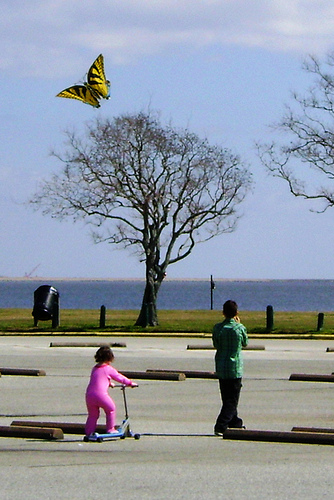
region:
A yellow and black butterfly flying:
[33, 61, 123, 112]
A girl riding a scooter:
[49, 324, 160, 445]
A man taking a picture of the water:
[196, 290, 271, 479]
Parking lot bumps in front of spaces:
[2, 356, 55, 392]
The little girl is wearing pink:
[81, 353, 148, 439]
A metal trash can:
[27, 256, 75, 342]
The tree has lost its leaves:
[48, 156, 246, 338]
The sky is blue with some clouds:
[166, 24, 261, 124]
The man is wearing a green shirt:
[205, 319, 258, 378]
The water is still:
[10, 263, 139, 304]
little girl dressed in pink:
[53, 309, 139, 464]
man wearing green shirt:
[190, 281, 273, 427]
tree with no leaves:
[66, 117, 242, 329]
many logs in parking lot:
[20, 319, 316, 482]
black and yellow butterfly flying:
[62, 66, 112, 107]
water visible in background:
[0, 255, 332, 310]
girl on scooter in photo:
[88, 350, 145, 455]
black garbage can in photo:
[23, 274, 87, 341]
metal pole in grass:
[198, 270, 225, 335]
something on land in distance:
[16, 256, 42, 284]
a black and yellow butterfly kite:
[56, 53, 111, 109]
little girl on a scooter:
[83, 342, 144, 440]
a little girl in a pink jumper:
[84, 345, 134, 432]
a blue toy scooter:
[83, 381, 139, 442]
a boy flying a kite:
[212, 299, 243, 430]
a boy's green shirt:
[211, 319, 248, 379]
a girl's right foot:
[104, 426, 120, 434]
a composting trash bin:
[31, 284, 60, 329]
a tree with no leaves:
[27, 113, 254, 325]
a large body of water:
[0, 281, 333, 308]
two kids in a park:
[67, 289, 265, 444]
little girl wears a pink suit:
[72, 338, 147, 450]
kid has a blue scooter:
[71, 337, 149, 450]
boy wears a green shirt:
[199, 290, 257, 444]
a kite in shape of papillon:
[53, 48, 129, 119]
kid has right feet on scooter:
[73, 340, 150, 452]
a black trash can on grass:
[24, 278, 67, 333]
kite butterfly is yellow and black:
[41, 48, 120, 114]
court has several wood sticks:
[9, 333, 332, 463]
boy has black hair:
[194, 291, 258, 442]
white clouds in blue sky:
[128, 19, 282, 86]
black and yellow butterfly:
[33, 49, 136, 115]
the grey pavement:
[112, 451, 213, 473]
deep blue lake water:
[89, 279, 133, 303]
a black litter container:
[17, 274, 68, 336]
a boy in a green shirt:
[209, 284, 247, 452]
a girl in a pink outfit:
[76, 333, 136, 440]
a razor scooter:
[80, 375, 147, 450]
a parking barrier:
[222, 426, 332, 452]